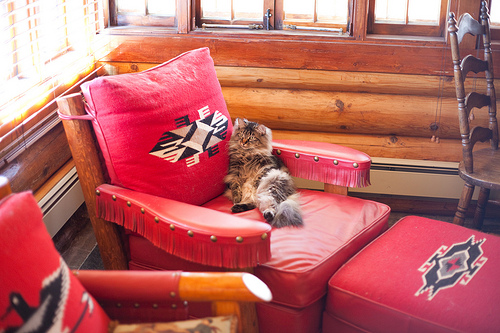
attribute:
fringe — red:
[92, 175, 279, 275]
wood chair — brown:
[440, 2, 498, 231]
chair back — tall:
[446, 0, 497, 171]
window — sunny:
[1, 0, 108, 108]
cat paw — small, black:
[230, 202, 250, 213]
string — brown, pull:
[428, 62, 448, 139]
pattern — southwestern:
[414, 225, 486, 306]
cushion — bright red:
[78, 46, 233, 206]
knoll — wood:
[309, 71, 384, 91]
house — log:
[253, 5, 443, 177]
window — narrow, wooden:
[380, 0, 434, 20]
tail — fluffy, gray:
[270, 194, 300, 223]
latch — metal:
[263, 13, 274, 33]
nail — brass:
[92, 187, 102, 197]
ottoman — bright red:
[322, 211, 499, 329]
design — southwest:
[412, 226, 492, 302]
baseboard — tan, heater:
[330, 154, 460, 206]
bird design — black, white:
[1, 259, 99, 330]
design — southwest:
[149, 108, 232, 166]